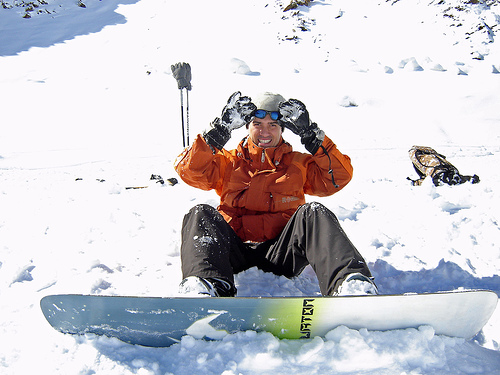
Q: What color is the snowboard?
A: White, blue, and yellow.